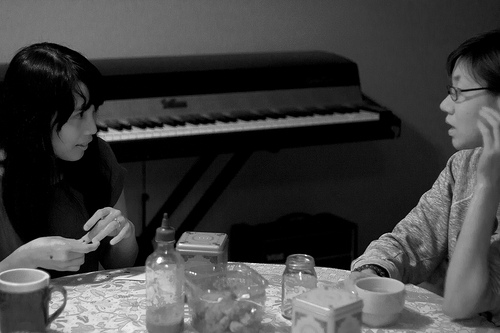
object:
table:
[46, 259, 500, 333]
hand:
[351, 270, 380, 283]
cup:
[353, 277, 406, 327]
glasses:
[444, 85, 497, 102]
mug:
[0, 268, 68, 333]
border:
[0, 268, 49, 293]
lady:
[340, 30, 499, 320]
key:
[96, 104, 378, 142]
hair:
[0, 42, 108, 245]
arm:
[441, 173, 499, 318]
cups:
[0, 213, 406, 333]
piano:
[67, 49, 400, 268]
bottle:
[144, 212, 186, 333]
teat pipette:
[155, 213, 175, 241]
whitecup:
[351, 277, 406, 327]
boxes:
[175, 231, 228, 303]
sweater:
[351, 147, 499, 326]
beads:
[351, 265, 385, 277]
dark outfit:
[0, 137, 129, 281]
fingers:
[110, 225, 130, 245]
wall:
[3, 4, 497, 240]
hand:
[476, 106, 500, 165]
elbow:
[441, 300, 475, 320]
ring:
[115, 218, 121, 228]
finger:
[92, 217, 124, 244]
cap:
[155, 213, 175, 241]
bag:
[180, 256, 266, 333]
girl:
[0, 41, 137, 279]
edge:
[284, 254, 316, 268]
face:
[51, 83, 98, 161]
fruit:
[195, 299, 262, 333]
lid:
[284, 254, 315, 269]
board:
[95, 105, 403, 164]